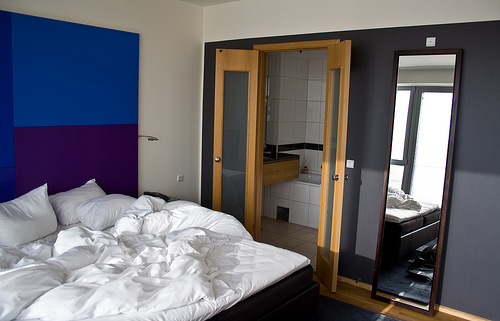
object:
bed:
[0, 220, 321, 320]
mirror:
[369, 48, 463, 316]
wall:
[199, 0, 498, 208]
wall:
[1, 0, 204, 204]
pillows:
[47, 177, 108, 226]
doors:
[255, 46, 332, 273]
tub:
[261, 172, 321, 231]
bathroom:
[258, 49, 328, 270]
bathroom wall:
[303, 51, 327, 175]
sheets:
[0, 193, 253, 321]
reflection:
[376, 54, 455, 311]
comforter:
[0, 194, 255, 321]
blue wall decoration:
[1, 10, 140, 127]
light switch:
[345, 159, 355, 169]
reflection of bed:
[386, 186, 423, 214]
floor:
[261, 215, 317, 270]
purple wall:
[13, 122, 139, 198]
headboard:
[0, 9, 141, 205]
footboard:
[204, 264, 322, 321]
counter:
[263, 153, 301, 186]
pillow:
[0, 183, 59, 248]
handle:
[331, 174, 340, 182]